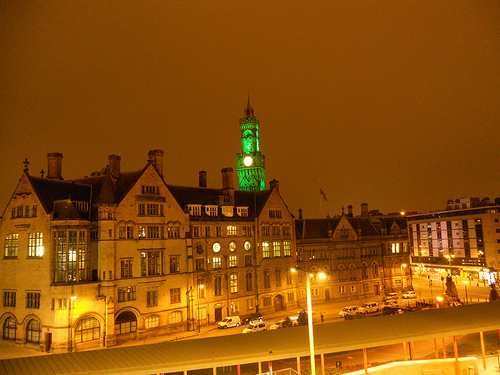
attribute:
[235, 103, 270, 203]
clock tower — green, lit up, sticking out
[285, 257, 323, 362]
street light — street , tall, on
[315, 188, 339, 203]
flag — hanging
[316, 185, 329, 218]
pole — tall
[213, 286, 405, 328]
cars — parked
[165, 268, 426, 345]
street — empty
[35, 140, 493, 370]
building — large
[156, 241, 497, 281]
lights — traffic, on, shining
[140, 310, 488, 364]
walkway — covered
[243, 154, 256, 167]
clock — white, bright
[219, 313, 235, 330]
van — white, parked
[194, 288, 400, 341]
vehicles — parked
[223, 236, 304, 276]
windows — several, three, round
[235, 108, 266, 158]
steeple — green, lit up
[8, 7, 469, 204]
sky — overcast, fading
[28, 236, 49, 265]
window — large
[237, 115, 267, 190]
light — green, white, small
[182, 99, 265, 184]
top — green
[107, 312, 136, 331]
window — curved, brown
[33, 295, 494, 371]
panel — brown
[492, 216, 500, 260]
ladder — black, tall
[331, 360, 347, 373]
trash can — tall, black